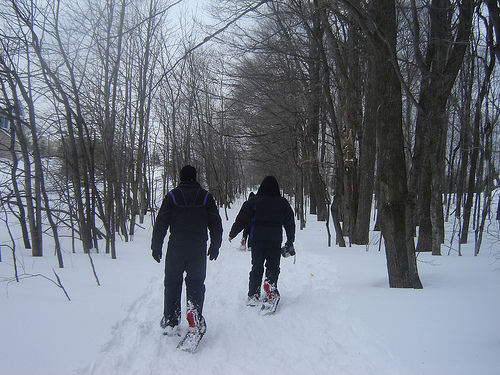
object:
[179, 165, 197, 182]
hat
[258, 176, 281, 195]
hat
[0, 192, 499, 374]
ground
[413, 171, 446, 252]
bark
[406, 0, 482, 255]
trunk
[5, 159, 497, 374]
white snow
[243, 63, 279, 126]
tree branches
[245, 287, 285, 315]
ski snow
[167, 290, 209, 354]
ski snow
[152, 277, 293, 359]
white skis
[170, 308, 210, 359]
claws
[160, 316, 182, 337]
claws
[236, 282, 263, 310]
claws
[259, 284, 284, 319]
claws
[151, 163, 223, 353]
man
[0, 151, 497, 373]
snow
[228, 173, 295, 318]
man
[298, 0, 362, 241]
trees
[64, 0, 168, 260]
trees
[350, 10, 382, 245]
trees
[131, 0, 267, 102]
branches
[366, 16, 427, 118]
branches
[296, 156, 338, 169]
branches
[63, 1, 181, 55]
branches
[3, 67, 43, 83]
branches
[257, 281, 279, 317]
ski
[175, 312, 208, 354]
ski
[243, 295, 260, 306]
ski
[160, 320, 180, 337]
ski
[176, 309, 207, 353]
board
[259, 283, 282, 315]
board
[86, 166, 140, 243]
big black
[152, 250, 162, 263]
gloves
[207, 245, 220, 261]
glove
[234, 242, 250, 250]
skis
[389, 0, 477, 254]
tree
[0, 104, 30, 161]
building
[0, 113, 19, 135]
windows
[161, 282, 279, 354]
panda claws